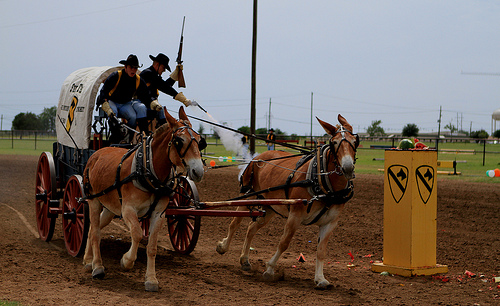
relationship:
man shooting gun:
[143, 53, 208, 123] [175, 15, 189, 87]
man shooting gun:
[143, 53, 208, 123] [186, 100, 208, 114]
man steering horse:
[102, 54, 154, 135] [75, 106, 205, 292]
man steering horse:
[102, 54, 154, 135] [213, 114, 360, 289]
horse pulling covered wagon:
[213, 114, 360, 289] [34, 65, 309, 260]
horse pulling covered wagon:
[75, 106, 205, 292] [34, 65, 309, 260]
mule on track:
[213, 105, 365, 290] [1, 150, 498, 305]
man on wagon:
[97, 54, 161, 145] [15, 72, 208, 257]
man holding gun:
[143, 53, 194, 128] [175, 15, 185, 87]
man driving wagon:
[97, 54, 161, 145] [26, 58, 311, 270]